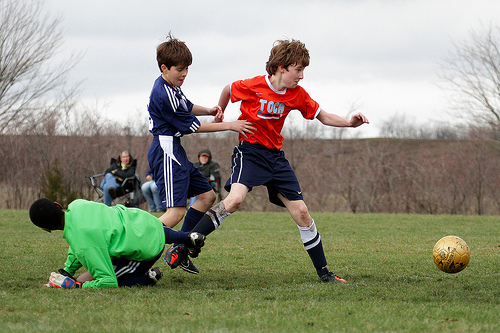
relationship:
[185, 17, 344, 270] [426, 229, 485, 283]
boy with ball